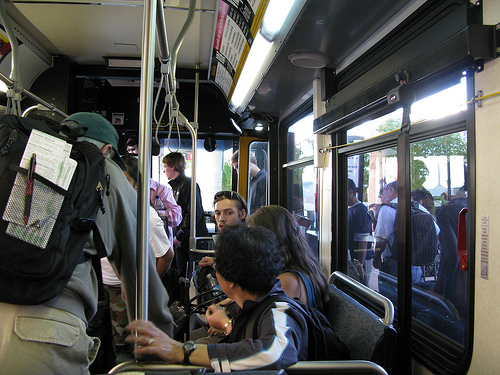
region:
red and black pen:
[20, 150, 40, 228]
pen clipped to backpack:
[20, 150, 39, 227]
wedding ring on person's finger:
[145, 337, 154, 345]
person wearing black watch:
[123, 220, 312, 373]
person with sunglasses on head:
[211, 185, 248, 230]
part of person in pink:
[122, 154, 183, 229]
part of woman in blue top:
[247, 201, 326, 309]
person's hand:
[202, 302, 234, 336]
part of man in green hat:
[0, 103, 180, 374]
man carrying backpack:
[0, 107, 178, 374]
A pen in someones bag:
[16, 159, 45, 199]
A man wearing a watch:
[174, 336, 199, 364]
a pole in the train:
[128, 252, 155, 297]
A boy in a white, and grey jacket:
[247, 341, 282, 373]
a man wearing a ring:
[138, 327, 156, 350]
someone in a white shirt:
[157, 219, 174, 250]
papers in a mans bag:
[54, 168, 81, 193]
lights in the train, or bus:
[240, 42, 278, 79]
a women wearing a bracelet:
[220, 312, 235, 333]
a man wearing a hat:
[79, 105, 114, 140]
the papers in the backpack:
[19, 113, 59, 226]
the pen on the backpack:
[22, 144, 39, 222]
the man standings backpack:
[11, 115, 81, 316]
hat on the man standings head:
[62, 101, 127, 173]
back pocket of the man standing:
[17, 310, 82, 356]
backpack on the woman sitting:
[262, 303, 365, 373]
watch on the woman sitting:
[178, 333, 194, 358]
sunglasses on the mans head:
[212, 186, 239, 208]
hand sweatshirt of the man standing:
[75, 162, 176, 338]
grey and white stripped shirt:
[219, 302, 309, 368]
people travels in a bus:
[5, 5, 495, 372]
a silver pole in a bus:
[131, 3, 164, 360]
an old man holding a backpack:
[0, 99, 152, 370]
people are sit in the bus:
[163, 198, 401, 374]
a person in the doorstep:
[220, 138, 272, 196]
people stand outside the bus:
[317, 133, 462, 317]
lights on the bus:
[213, 0, 299, 115]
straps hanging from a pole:
[147, 50, 190, 157]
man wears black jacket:
[159, 148, 214, 237]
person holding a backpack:
[359, 168, 441, 278]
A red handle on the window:
[454, 207, 474, 273]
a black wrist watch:
[181, 340, 196, 360]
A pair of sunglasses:
[211, 188, 246, 210]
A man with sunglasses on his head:
[191, 190, 255, 294]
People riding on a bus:
[6, 65, 414, 373]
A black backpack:
[2, 109, 112, 309]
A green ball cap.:
[61, 107, 134, 169]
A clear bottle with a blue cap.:
[152, 193, 164, 211]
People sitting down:
[173, 190, 366, 373]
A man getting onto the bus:
[157, 146, 224, 265]